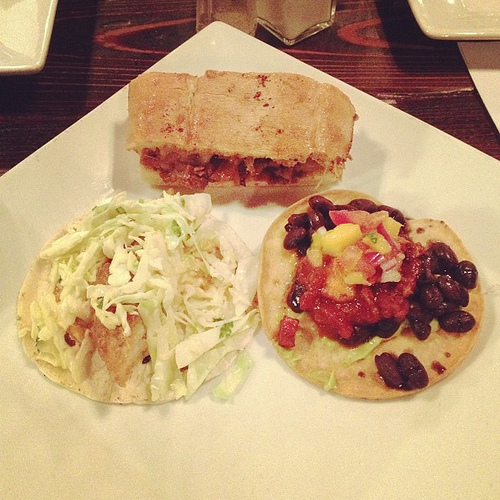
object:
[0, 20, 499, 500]
plate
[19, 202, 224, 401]
tortilla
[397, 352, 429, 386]
beans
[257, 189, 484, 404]
tortilla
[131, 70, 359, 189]
bread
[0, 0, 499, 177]
table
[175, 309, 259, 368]
lettuce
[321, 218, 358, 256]
pineapple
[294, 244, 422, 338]
salsa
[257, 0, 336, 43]
salt shaker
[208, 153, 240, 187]
meat